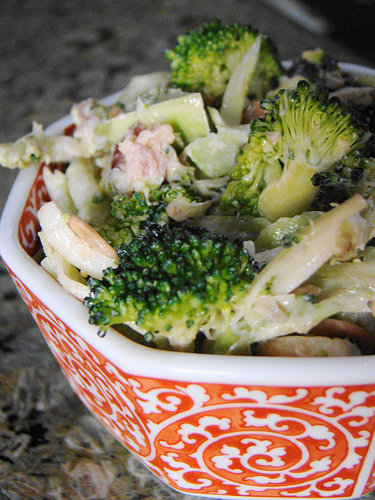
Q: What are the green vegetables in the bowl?
A: Broccoli.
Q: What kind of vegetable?
A: Broccoli.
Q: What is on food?
A: Sauce.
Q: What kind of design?
A: White and orange.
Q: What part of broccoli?
A: Top.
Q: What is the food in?
A: Bowl.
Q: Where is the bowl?
A: Table.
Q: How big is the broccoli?
A: Large.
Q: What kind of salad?
A: Pasta.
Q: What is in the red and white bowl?
A: Salad.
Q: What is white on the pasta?
A: Sauce.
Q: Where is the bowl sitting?
A: On the table.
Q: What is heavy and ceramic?
A: The bowl.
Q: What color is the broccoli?
A: Green.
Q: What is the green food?
A: Broccoli.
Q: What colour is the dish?
A: White and red.